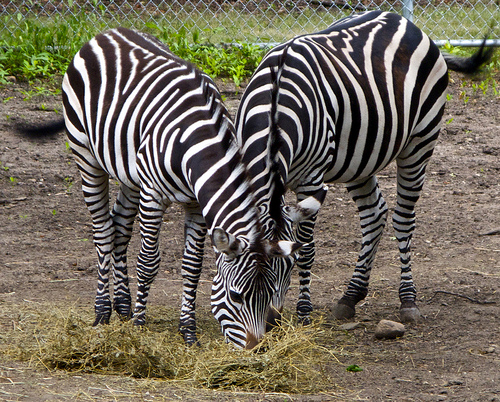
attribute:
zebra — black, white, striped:
[211, 8, 450, 342]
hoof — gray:
[326, 287, 364, 326]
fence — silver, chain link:
[1, 1, 497, 62]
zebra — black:
[9, 23, 327, 361]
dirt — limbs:
[417, 305, 484, 392]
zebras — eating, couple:
[64, 6, 459, 348]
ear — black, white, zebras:
[280, 174, 333, 227]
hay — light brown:
[7, 316, 326, 399]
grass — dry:
[0, 298, 356, 394]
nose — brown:
[247, 329, 272, 354]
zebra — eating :
[221, 11, 492, 330]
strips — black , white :
[349, 54, 399, 129]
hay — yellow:
[32, 316, 332, 391]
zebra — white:
[60, 22, 277, 359]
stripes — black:
[181, 123, 196, 136]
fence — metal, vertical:
[399, 0, 421, 50]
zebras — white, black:
[239, 8, 419, 326]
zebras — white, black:
[54, 18, 262, 339]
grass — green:
[5, 15, 265, 90]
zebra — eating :
[55, 25, 305, 352]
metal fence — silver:
[134, 4, 299, 66]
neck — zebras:
[170, 91, 274, 278]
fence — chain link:
[4, 5, 498, 65]